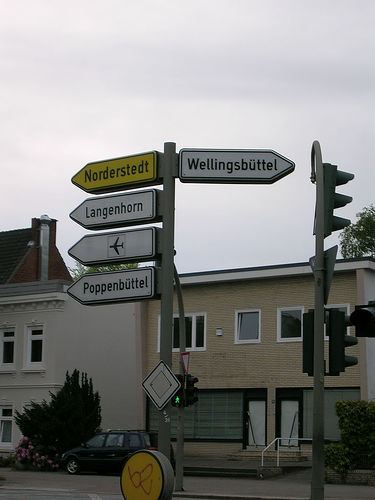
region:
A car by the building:
[68, 429, 160, 470]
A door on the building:
[248, 398, 267, 445]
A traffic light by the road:
[172, 375, 196, 406]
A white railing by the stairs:
[260, 437, 315, 465]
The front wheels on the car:
[65, 460, 77, 470]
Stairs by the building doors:
[231, 446, 297, 457]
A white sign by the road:
[143, 360, 178, 406]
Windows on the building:
[1, 325, 43, 365]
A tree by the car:
[11, 370, 102, 457]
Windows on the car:
[90, 432, 148, 446]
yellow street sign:
[69, 152, 159, 187]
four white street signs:
[70, 141, 294, 308]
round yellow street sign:
[114, 447, 167, 497]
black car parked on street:
[62, 429, 161, 476]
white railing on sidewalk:
[257, 437, 325, 470]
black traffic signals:
[291, 309, 359, 385]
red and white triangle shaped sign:
[178, 347, 194, 377]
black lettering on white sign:
[72, 191, 156, 226]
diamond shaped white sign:
[142, 359, 179, 412]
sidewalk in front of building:
[180, 445, 321, 477]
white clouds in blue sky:
[11, 24, 51, 79]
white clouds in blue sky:
[92, 40, 152, 86]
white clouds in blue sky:
[191, 20, 240, 83]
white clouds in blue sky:
[203, 212, 231, 245]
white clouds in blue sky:
[245, 201, 279, 248]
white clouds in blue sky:
[277, 45, 326, 96]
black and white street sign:
[71, 195, 165, 226]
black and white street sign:
[70, 262, 151, 298]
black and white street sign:
[62, 231, 175, 261]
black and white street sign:
[184, 141, 293, 188]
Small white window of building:
[230, 303, 266, 357]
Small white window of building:
[269, 298, 304, 347]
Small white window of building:
[314, 302, 355, 348]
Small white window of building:
[193, 307, 210, 354]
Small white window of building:
[168, 311, 192, 360]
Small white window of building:
[24, 318, 57, 376]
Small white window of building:
[0, 401, 17, 421]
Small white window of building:
[1, 422, 16, 448]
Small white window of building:
[0, 323, 25, 383]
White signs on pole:
[40, 128, 180, 329]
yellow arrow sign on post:
[70, 153, 157, 192]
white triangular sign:
[142, 359, 181, 411]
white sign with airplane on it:
[67, 225, 157, 258]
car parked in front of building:
[60, 431, 159, 471]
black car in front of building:
[61, 430, 156, 475]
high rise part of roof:
[4, 215, 69, 279]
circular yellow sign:
[120, 449, 172, 498]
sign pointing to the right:
[181, 146, 295, 184]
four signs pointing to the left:
[60, 150, 155, 306]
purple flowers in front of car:
[14, 435, 62, 468]